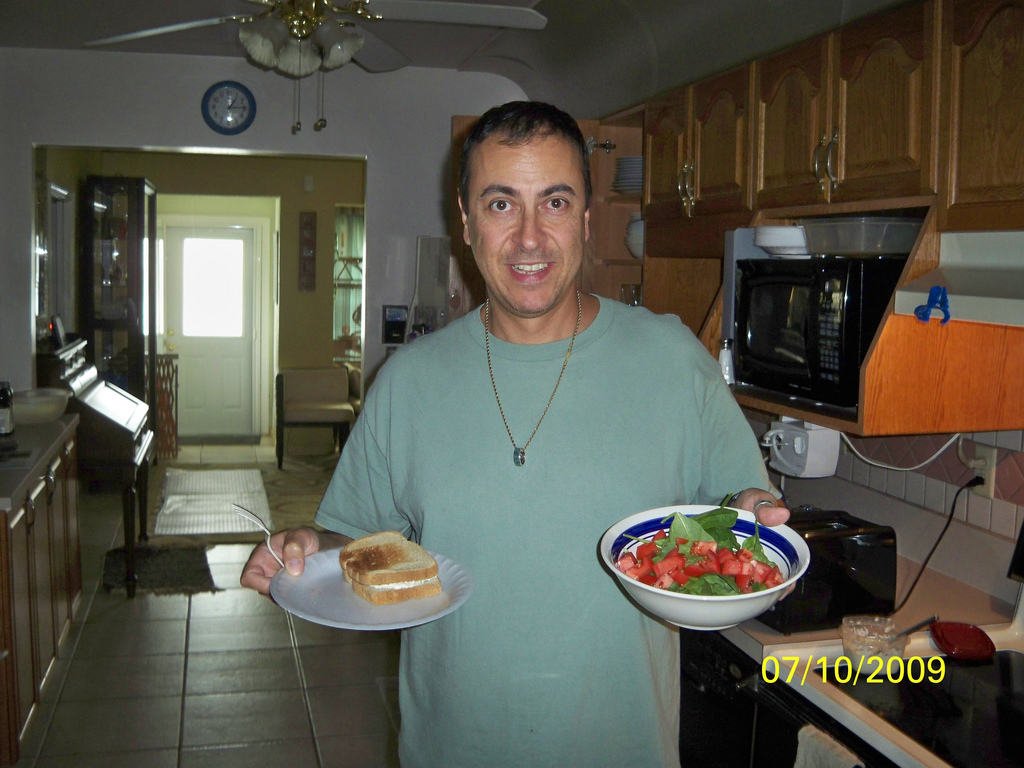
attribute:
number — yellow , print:
[767, 631, 815, 684]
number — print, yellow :
[802, 633, 846, 692]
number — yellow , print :
[879, 646, 906, 696]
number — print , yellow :
[894, 646, 934, 690]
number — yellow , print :
[923, 644, 960, 692]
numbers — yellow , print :
[760, 639, 808, 692]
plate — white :
[261, 520, 476, 639]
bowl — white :
[596, 484, 823, 640]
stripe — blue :
[609, 492, 804, 599]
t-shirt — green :
[331, 253, 781, 763]